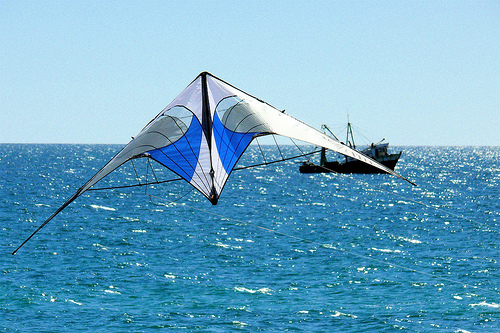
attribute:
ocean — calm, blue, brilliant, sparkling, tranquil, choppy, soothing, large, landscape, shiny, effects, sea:
[3, 144, 497, 332]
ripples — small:
[115, 212, 271, 261]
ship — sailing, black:
[306, 113, 402, 177]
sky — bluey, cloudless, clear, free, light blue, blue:
[2, 2, 494, 143]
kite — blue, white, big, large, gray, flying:
[10, 72, 420, 266]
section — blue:
[209, 91, 252, 116]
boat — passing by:
[300, 136, 404, 174]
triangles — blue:
[147, 115, 252, 179]